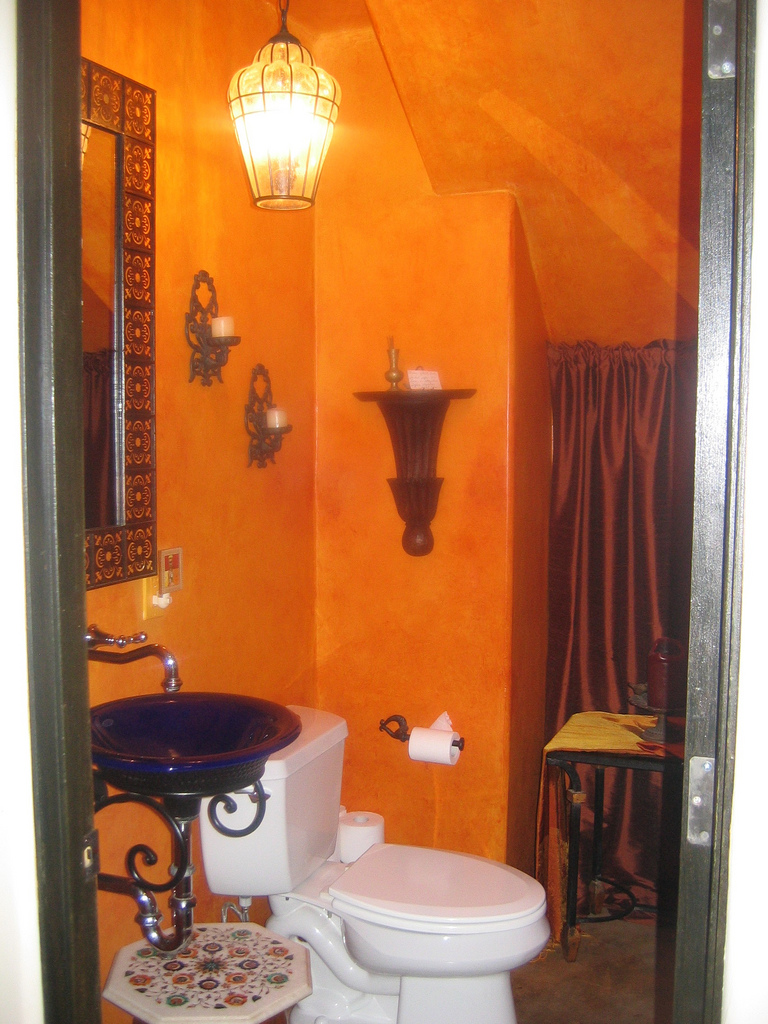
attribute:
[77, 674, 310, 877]
sink — blue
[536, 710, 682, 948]
table — black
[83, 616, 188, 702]
faucet — silver, metal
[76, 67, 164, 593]
mirror frame — colorful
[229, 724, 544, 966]
toilet — white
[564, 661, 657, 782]
cloth — yellow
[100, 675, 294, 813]
skin — blue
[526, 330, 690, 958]
curtain — dark brown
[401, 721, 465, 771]
toilet paper — white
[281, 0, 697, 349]
ceiling — orange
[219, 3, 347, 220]
light — hanging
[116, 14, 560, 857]
wall — orange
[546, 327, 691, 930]
curtain — red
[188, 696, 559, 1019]
toilet — white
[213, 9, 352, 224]
light — on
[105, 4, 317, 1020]
wall — orange